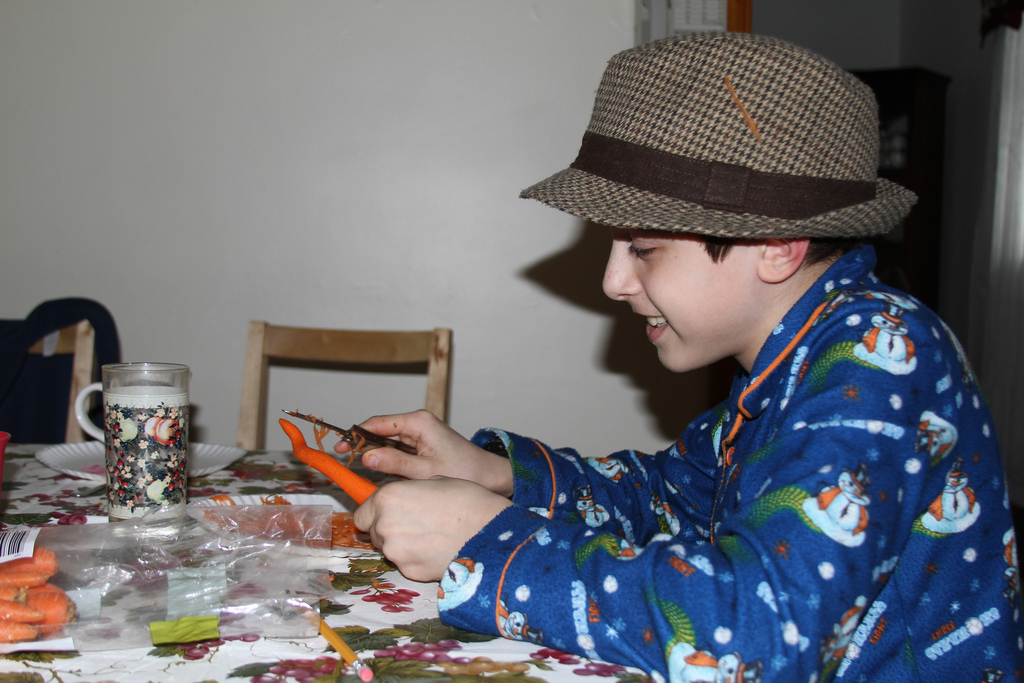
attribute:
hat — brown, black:
[584, 48, 839, 250]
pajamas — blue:
[638, 498, 822, 602]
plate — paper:
[44, 437, 138, 528]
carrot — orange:
[278, 385, 371, 494]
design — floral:
[135, 422, 177, 500]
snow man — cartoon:
[809, 452, 881, 563]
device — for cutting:
[241, 349, 401, 488]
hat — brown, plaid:
[533, 16, 840, 207]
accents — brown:
[627, 70, 720, 198]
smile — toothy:
[636, 299, 699, 358]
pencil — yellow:
[299, 584, 351, 678]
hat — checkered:
[530, 27, 870, 237]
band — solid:
[576, 96, 769, 209]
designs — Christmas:
[128, 403, 167, 505]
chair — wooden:
[249, 344, 425, 425]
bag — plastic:
[7, 530, 109, 673]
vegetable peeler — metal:
[280, 400, 386, 467]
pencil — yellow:
[271, 569, 388, 678]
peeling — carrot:
[250, 493, 352, 578]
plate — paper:
[202, 486, 369, 605]